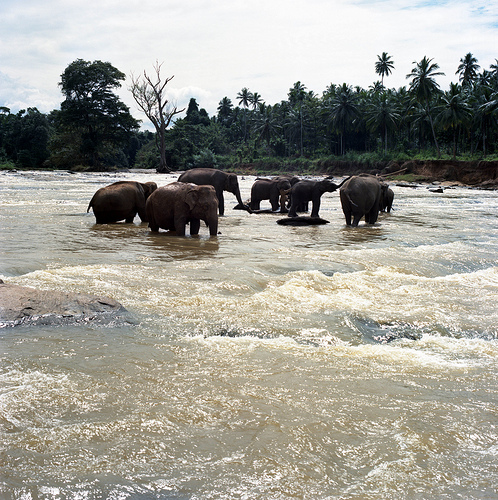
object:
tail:
[341, 188, 359, 209]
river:
[0, 167, 497, 499]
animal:
[248, 176, 292, 212]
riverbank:
[212, 157, 498, 191]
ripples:
[111, 254, 160, 280]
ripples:
[0, 322, 68, 359]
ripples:
[392, 431, 438, 453]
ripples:
[46, 413, 169, 439]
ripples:
[191, 333, 300, 350]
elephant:
[146, 181, 224, 235]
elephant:
[87, 181, 158, 225]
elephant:
[178, 167, 246, 216]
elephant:
[284, 175, 354, 218]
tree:
[433, 88, 472, 155]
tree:
[323, 83, 363, 157]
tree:
[280, 101, 316, 155]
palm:
[426, 57, 440, 74]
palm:
[374, 55, 382, 66]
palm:
[405, 67, 416, 82]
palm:
[289, 87, 299, 99]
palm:
[249, 113, 266, 125]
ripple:
[48, 450, 154, 499]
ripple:
[127, 444, 257, 488]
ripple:
[230, 433, 326, 497]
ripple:
[356, 415, 418, 498]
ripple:
[4, 360, 98, 415]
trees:
[0, 56, 153, 175]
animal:
[338, 176, 394, 226]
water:
[0, 171, 497, 500]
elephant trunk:
[205, 210, 218, 236]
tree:
[126, 58, 187, 175]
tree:
[373, 51, 396, 90]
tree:
[287, 78, 307, 109]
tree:
[181, 97, 211, 129]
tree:
[235, 86, 256, 112]